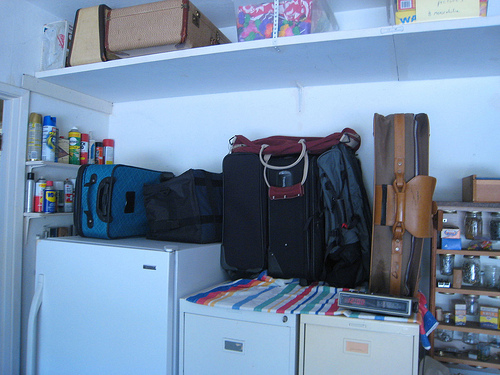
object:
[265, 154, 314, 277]
suitcases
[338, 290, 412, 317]
clock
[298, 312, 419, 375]
file cabinet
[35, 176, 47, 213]
can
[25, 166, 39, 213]
can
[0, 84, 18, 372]
door frame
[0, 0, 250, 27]
ceiling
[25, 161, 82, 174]
shelf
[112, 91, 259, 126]
wall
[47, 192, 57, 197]
wd-40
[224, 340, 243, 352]
handle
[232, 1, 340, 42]
clothes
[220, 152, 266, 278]
suitcase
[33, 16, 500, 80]
shelf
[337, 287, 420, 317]
alarm clock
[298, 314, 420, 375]
cabinet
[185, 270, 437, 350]
blanket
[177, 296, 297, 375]
cabinet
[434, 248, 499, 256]
shelf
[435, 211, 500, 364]
supplies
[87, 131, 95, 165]
cans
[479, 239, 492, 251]
trinket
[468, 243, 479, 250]
trinket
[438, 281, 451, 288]
trinket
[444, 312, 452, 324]
trinket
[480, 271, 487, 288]
trinket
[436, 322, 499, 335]
shelf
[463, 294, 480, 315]
jar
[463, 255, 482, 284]
jar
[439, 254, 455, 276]
jar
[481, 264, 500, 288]
jar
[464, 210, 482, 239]
jar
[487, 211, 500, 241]
jar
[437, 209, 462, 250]
jar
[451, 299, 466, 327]
jar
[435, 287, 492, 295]
shelf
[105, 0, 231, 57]
suitcase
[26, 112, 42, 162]
spraypaint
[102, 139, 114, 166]
can shelf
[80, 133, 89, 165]
can shelf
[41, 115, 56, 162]
can shelf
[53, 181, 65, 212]
can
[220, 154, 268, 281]
suit case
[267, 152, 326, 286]
suit case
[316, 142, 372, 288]
suit case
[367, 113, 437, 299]
suit case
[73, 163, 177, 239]
suit case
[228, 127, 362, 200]
bag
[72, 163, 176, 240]
tote bag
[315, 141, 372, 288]
suitcase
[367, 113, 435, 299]
suitcase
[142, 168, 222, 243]
suitcase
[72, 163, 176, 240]
suitcase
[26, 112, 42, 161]
can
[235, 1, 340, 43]
storage bin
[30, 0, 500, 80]
top shelf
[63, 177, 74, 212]
can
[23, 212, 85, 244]
shelf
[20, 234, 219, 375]
fridge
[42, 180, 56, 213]
can